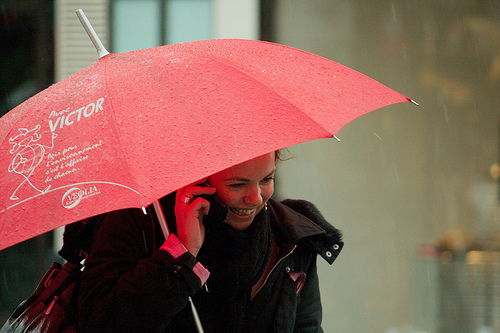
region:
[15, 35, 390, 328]
woman holding red umbrella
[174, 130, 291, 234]
woman smiling while on cell phone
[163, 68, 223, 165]
rain drops on top of umbrella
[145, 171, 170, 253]
silver handle of umbrella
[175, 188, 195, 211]
ring on womans right hand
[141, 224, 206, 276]
pink cuffs on black jacket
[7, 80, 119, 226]
silver lettering on red umbrella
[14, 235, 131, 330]
handbag on woman's shoulder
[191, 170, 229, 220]
black cell phone in woman's right hand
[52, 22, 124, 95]
white shutters behind woman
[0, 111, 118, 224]
a logo on an umbrella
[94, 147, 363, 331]
a woman using her phone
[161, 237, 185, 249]
pink trim on a black sleeve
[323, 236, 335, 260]
metal snaps on a hood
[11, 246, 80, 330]
a purse hanging on a shoulder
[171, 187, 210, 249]
a hand wearing a wedding band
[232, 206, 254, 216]
white teeth in a pink mouth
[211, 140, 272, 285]
a woman wearing a black scarf and jacket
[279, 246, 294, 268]
a metal zipper on a jacket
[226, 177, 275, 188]
two eyes on a face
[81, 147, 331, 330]
girl on cell phone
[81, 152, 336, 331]
girl under umbrella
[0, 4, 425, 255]
red umbrella being held by woman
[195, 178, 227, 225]
cell phone being held by woman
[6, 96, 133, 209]
advertising on red umbrella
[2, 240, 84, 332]
bag being carried by woman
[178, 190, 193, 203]
ring on woman's finger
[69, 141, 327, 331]
woman carrying a bag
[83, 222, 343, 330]
jacket being worn by woman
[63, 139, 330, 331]
woman walking in rain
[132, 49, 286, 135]
A wet red umbrella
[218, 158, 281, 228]
A woman with earrings on smiling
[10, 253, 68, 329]
A black purse with zipper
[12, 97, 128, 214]
A logo on the red umbrella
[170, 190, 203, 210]
A silver ring on a finger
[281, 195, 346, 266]
A black jacket collar with silver snaps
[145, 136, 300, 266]
A woman using a phone under the umbrella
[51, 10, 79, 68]
Blurred white window shutters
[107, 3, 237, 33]
A window behind the woman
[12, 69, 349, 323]
A woman wearing a black jacket walking with an umbrella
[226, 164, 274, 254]
Woman in black shirt smiling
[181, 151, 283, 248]
Woman on phone smiling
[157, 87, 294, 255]
Woman smiling and carrying umbrella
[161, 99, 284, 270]
Woman on phone carrying red umbrella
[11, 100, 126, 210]
Advertisment on red umbrella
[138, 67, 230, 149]
Raindrops on red umbrella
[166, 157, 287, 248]
Woman on phone wearing a ring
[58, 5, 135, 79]
Silver top on red umbrella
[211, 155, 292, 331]
Woman wearing a black jacket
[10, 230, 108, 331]
Woman carrying black handbag